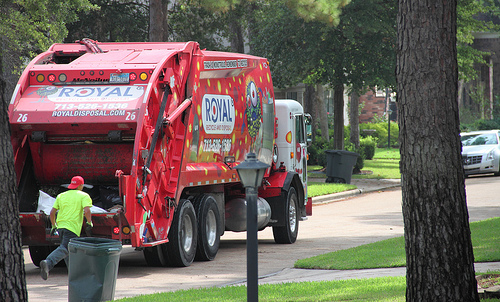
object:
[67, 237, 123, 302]
trash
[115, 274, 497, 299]
grass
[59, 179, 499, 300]
sidewalk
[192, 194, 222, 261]
wheels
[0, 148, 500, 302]
ground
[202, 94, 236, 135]
sign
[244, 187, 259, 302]
post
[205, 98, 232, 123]
word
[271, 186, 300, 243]
tire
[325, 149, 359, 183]
trash can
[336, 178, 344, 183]
wheels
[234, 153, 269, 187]
lamp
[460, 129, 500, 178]
parked car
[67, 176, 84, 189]
hat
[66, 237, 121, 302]
can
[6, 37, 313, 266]
garbage truck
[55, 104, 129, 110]
phone number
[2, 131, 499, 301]
street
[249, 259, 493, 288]
driveway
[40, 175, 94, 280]
bears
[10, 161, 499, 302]
road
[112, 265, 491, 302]
yard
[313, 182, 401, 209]
corner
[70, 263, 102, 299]
dent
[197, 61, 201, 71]
dots